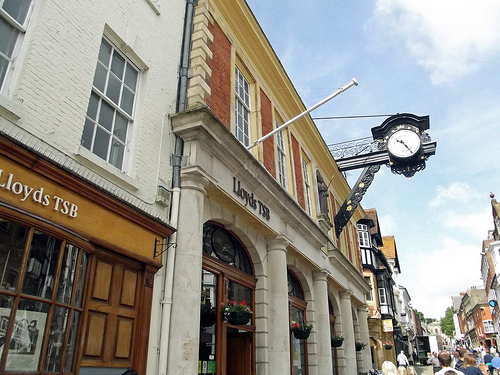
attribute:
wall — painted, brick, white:
[2, 1, 179, 217]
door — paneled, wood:
[80, 248, 145, 371]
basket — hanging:
[229, 302, 255, 327]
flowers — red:
[230, 300, 251, 309]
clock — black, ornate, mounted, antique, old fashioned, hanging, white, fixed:
[367, 112, 437, 178]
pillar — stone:
[170, 175, 209, 373]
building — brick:
[187, 0, 372, 374]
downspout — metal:
[158, 0, 200, 374]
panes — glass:
[81, 97, 141, 157]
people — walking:
[438, 340, 499, 374]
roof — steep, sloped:
[366, 207, 379, 233]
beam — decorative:
[335, 151, 388, 171]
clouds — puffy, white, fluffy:
[388, 1, 484, 86]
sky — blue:
[283, 17, 367, 68]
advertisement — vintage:
[3, 306, 42, 371]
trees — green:
[434, 311, 456, 338]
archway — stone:
[204, 201, 271, 264]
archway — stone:
[283, 252, 318, 312]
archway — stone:
[324, 285, 342, 313]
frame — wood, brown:
[5, 206, 107, 252]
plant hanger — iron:
[227, 309, 252, 327]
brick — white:
[38, 114, 49, 123]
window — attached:
[231, 59, 335, 215]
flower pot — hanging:
[225, 303, 254, 319]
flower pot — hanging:
[296, 322, 312, 339]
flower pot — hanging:
[332, 334, 344, 346]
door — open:
[224, 333, 251, 373]